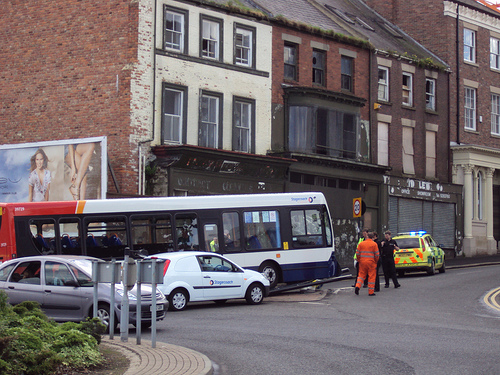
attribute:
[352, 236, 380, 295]
suit — orange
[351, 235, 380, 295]
jumpsuit — orange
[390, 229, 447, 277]
car — yellow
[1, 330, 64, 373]
bush — green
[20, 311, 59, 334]
bush — green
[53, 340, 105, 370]
bush — green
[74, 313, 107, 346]
bush — green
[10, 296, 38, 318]
bush — green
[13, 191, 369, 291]
bus — long, red, blue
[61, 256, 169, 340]
signs — grouped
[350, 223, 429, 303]
men — grouped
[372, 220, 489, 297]
vehicle — emergency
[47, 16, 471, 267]
building — white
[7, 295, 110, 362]
bushes — grouped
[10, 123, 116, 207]
ad — feminine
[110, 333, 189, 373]
stones — brown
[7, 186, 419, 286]
bus — orange, striped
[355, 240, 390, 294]
jumpsuit — orange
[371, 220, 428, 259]
cab — yellow, orange, parked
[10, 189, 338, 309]
bus — large, parked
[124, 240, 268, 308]
car — white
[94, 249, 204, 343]
signs — metal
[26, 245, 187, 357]
car — gray, parked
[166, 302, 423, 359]
paving — circular, brick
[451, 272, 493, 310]
lines — yellow, solid, double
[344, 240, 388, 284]
jumpsuit — orange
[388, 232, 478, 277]
vehicle — neon yellow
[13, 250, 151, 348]
vehicle — four door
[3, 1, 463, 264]
building — three-story, brick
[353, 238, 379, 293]
clothes — orange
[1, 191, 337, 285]
bus — red, white, blue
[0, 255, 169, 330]
car — gray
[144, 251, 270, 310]
car — white